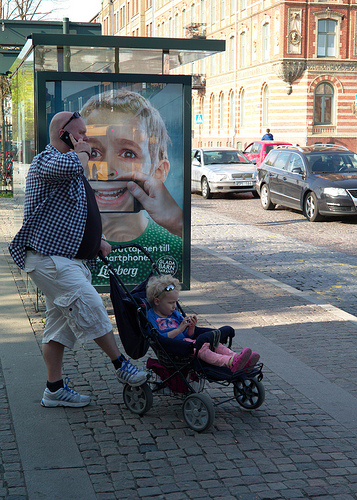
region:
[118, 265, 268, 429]
small kid in stroller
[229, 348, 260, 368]
pink shoes on feet of kid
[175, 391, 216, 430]
small wheel on stroller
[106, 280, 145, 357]
black bag on back of stroller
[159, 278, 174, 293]
sunglasses on head of kid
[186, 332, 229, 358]
pink pants on legs of kid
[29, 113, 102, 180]
man talking on cell phone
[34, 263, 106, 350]
long cargo shorts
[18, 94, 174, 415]
man holding stroller of kid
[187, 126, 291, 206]
cars driving on the road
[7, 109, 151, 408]
Man talking on a cellphone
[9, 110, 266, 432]
Man pushing a stroller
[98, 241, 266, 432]
Girl sitting in a black stroller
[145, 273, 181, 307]
Blonde hair and sunglasses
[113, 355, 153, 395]
Foot resting on a stroller wheel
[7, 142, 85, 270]
Black and white checkered shirt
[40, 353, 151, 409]
Black socks sticking out of white shoes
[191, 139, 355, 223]
Vehicles driving on a street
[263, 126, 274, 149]
Person walking on a sidewalk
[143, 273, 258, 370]
Girl wearing a blue shirt and pink pants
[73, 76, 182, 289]
advertisement on bus stop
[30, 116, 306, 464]
man pushing a stroller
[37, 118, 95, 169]
man talking on cellphone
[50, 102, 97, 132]
man wearing sunglasses on head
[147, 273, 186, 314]
little girl wearing sunglasses on head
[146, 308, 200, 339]
little girl wearing a blue shirt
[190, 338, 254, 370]
little girl wearing pink pants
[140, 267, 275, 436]
little girl on stroller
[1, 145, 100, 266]
man wearing a checkered shirt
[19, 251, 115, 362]
man wearing khaki pants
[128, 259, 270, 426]
Little girl sitting in stroller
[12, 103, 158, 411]
Man wearing a plaid shirt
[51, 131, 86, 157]
Phone on man's ear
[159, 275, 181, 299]
Headband on girls head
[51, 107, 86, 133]
Glasses on man's head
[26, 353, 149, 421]
Sneakers on man's feet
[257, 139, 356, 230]
Black car in the street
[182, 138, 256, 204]
Gray car in the street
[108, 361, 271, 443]
Wheels on the stroller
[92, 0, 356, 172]
Building in the background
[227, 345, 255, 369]
a girl's pink shoe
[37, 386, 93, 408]
a man's tennis shoe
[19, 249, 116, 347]
a man's brown shorts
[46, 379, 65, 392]
a man's black sock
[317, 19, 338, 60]
a window of a building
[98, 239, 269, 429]
a baby stroller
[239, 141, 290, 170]
part of a red car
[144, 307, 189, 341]
a girl's blue shirt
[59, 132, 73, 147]
part of a cellphone